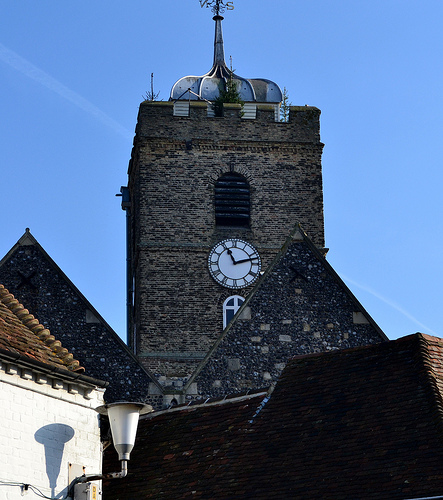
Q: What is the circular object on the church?
A: A clock.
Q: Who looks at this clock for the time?
A: Church members.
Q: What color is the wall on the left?
A: White.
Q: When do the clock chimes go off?
A: On the hour.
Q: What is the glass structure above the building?
A: A dome.